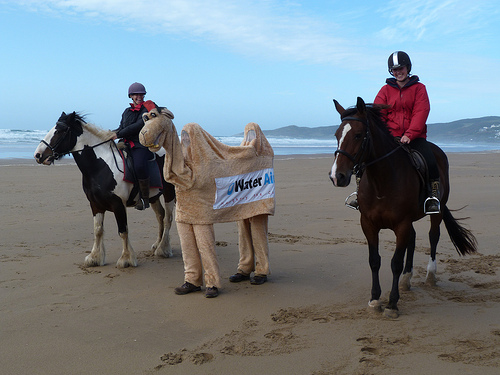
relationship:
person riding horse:
[344, 49, 441, 218] [322, 93, 474, 312]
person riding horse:
[104, 71, 172, 204] [29, 108, 189, 278]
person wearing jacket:
[344, 49, 441, 218] [362, 73, 431, 153]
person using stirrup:
[344, 49, 441, 218] [413, 188, 453, 221]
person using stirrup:
[344, 49, 441, 218] [339, 187, 368, 216]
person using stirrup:
[104, 71, 172, 204] [134, 192, 154, 216]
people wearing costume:
[136, 100, 291, 301] [136, 106, 291, 288]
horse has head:
[322, 93, 474, 312] [315, 89, 383, 192]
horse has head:
[29, 108, 189, 278] [28, 107, 88, 172]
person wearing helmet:
[344, 49, 441, 218] [381, 44, 421, 78]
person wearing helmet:
[104, 71, 172, 204] [126, 78, 149, 103]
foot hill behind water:
[235, 109, 499, 150] [1, 125, 500, 167]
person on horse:
[344, 49, 441, 218] [322, 93, 474, 312]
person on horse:
[104, 71, 172, 204] [29, 108, 189, 278]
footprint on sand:
[189, 352, 211, 365] [0, 151, 499, 373]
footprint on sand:
[357, 335, 375, 345] [0, 151, 499, 373]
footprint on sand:
[359, 356, 380, 368] [0, 151, 499, 373]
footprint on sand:
[161, 352, 181, 364] [0, 151, 499, 373]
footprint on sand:
[313, 317, 334, 326] [0, 151, 499, 373]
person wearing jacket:
[360, 33, 442, 153] [369, 83, 443, 145]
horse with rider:
[322, 93, 474, 312] [377, 47, 442, 216]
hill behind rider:
[276, 116, 491, 156] [367, 48, 443, 216]